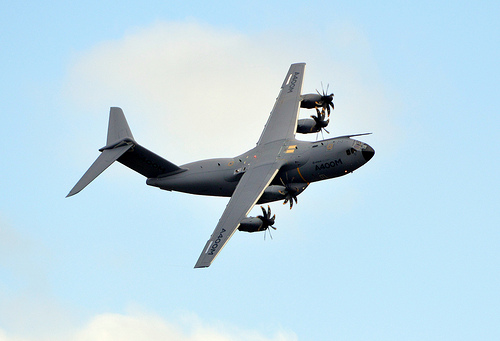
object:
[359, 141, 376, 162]
nose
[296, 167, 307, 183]
stripe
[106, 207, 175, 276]
clouds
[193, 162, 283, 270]
wing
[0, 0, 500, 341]
blue sky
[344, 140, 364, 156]
cockpit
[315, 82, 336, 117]
propeller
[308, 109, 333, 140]
propeller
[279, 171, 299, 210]
propeller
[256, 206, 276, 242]
propeller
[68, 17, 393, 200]
cloud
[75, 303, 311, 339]
cloud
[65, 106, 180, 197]
tail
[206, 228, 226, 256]
mark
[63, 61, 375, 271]
airplane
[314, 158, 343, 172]
writing